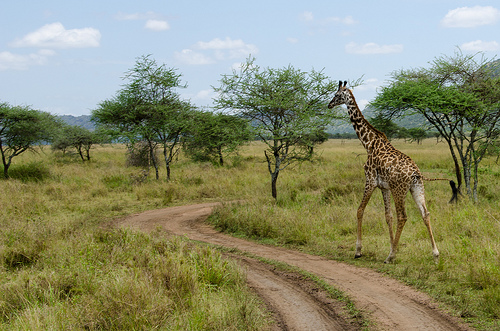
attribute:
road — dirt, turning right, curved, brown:
[118, 199, 467, 330]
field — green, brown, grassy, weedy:
[2, 137, 499, 330]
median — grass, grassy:
[203, 236, 367, 328]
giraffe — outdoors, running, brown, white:
[328, 78, 447, 263]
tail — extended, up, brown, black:
[415, 169, 462, 203]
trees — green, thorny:
[4, 68, 326, 177]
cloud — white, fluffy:
[21, 20, 101, 49]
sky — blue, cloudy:
[1, 1, 498, 108]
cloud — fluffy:
[184, 39, 250, 64]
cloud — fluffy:
[443, 6, 498, 27]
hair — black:
[448, 178, 462, 204]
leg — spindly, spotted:
[355, 185, 371, 260]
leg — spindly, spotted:
[381, 188, 395, 253]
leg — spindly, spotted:
[388, 181, 408, 261]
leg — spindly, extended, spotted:
[411, 177, 441, 261]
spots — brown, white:
[375, 146, 396, 176]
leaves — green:
[250, 76, 327, 112]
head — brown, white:
[328, 80, 351, 108]